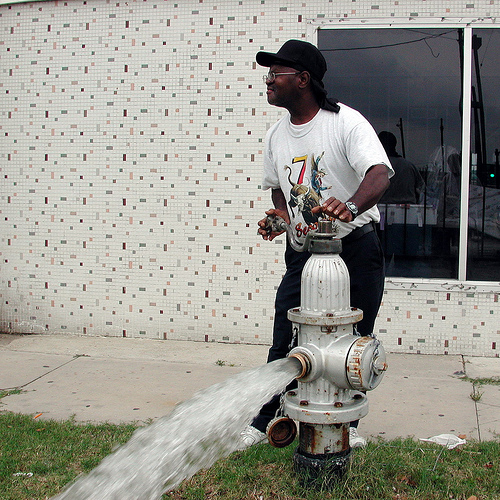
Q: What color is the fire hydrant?
A: White.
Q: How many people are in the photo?
A: 1.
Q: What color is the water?
A: White.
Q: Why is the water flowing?
A: The man opened the spicket.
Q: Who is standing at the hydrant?
A: The man.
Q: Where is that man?
A: At the hydrant.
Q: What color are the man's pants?
A: Black.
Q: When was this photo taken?
A: During the day.